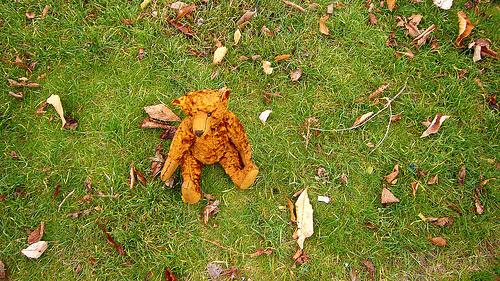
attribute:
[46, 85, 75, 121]
leaf — small, brown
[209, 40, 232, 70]
leaf — brown, small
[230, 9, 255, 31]
leaf — small, brown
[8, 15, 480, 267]
grass — green